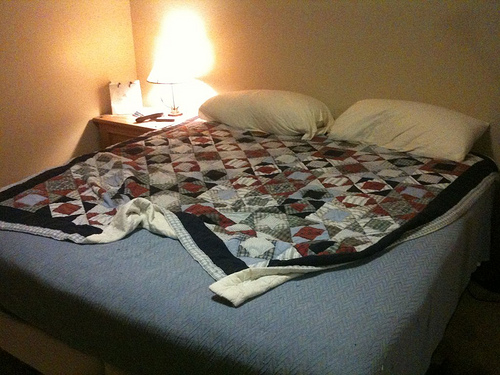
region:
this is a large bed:
[4, 72, 491, 371]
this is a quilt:
[9, 78, 494, 329]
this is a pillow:
[326, 83, 485, 171]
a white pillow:
[196, 79, 335, 147]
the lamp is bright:
[131, 22, 223, 100]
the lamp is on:
[132, 12, 267, 113]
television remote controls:
[125, 102, 181, 126]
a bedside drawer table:
[99, 114, 200, 145]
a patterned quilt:
[1, 123, 472, 282]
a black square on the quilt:
[292, 181, 332, 203]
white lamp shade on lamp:
[151, 28, 204, 85]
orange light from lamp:
[143, 36, 205, 96]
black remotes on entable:
[135, 105, 169, 125]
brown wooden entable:
[81, 118, 142, 145]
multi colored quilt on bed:
[268, 156, 373, 238]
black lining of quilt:
[358, 210, 428, 268]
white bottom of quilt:
[218, 268, 275, 299]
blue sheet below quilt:
[250, 284, 387, 374]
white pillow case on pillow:
[337, 79, 494, 175]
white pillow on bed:
[246, 79, 324, 133]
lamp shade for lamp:
[152, 10, 214, 93]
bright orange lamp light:
[152, 36, 199, 96]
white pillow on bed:
[198, 84, 320, 161]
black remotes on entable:
[138, 112, 183, 127]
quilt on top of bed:
[123, 114, 428, 275]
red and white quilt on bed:
[288, 165, 311, 182]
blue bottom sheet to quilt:
[250, 273, 399, 373]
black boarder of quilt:
[200, 223, 264, 298]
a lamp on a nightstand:
[146, 31, 194, 120]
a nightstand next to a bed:
[92, 102, 196, 155]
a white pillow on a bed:
[196, 88, 334, 146]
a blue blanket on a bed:
[0, 188, 497, 371]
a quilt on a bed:
[1, 114, 494, 307]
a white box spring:
[0, 312, 102, 373]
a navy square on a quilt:
[302, 186, 327, 203]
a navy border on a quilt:
[265, 158, 495, 297]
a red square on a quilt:
[52, 199, 82, 216]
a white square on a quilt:
[239, 233, 275, 258]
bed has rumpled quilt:
[6, 25, 498, 374]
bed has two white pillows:
[8, 22, 494, 373]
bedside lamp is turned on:
[131, 17, 225, 124]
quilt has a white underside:
[4, 37, 497, 327]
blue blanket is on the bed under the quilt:
[4, 69, 498, 369]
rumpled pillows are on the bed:
[1, 41, 478, 374]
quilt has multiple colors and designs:
[0, 64, 498, 333]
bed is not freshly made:
[5, 36, 498, 372]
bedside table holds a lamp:
[85, 6, 211, 141]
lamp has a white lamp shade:
[127, 21, 202, 133]